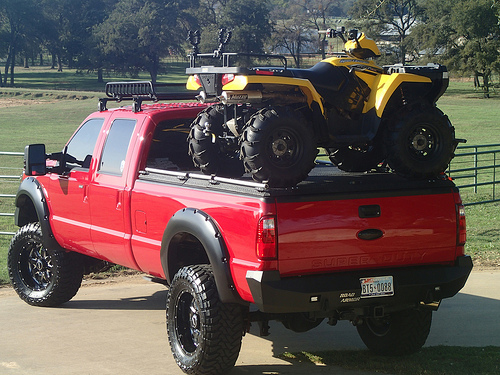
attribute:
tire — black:
[362, 91, 469, 180]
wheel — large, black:
[164, 264, 242, 373]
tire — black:
[319, 141, 383, 177]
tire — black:
[229, 95, 323, 196]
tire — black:
[163, 259, 244, 369]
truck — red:
[10, 77, 476, 373]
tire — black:
[184, 96, 247, 181]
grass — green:
[5, 100, 77, 128]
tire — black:
[2, 219, 82, 315]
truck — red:
[1, 79, 450, 364]